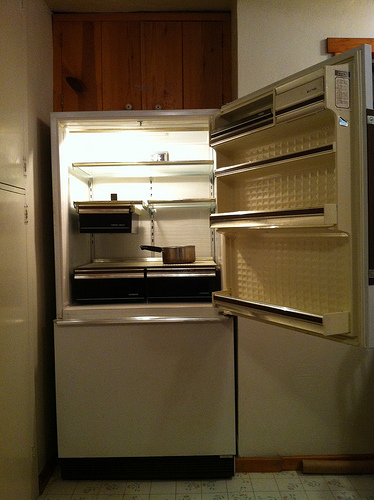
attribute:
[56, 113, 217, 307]
refrigerator — open, white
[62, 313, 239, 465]
freezer — bottom, white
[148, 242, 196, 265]
pan — metal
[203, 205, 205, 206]
drawers — black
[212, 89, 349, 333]
door — open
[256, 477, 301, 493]
flooring — white, tiled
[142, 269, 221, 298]
drawer — black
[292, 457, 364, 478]
tube — cardboard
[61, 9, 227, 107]
cabinets — wooden, white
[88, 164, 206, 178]
shelf — glass, empty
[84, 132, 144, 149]
light — shining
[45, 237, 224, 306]
fridge — open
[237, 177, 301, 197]
wall — yellow